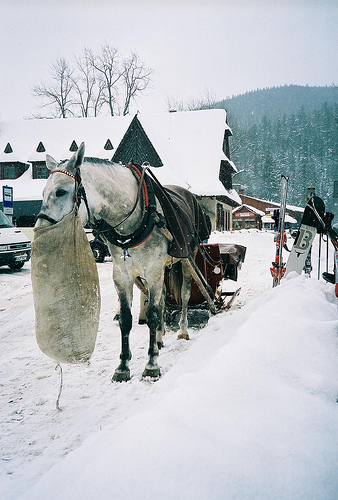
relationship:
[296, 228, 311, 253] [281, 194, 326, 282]
letter on snowboard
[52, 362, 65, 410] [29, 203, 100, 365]
string on feed bag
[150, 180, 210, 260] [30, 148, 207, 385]
blanket over horse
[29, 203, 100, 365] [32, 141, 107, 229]
feed bag on a head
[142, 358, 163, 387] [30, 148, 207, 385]
hoof of horse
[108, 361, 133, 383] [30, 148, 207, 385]
hoof of horse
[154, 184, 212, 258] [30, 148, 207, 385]
blanket over horse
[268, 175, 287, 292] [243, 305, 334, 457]
skis planted in ground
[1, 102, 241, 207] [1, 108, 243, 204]
snow on roof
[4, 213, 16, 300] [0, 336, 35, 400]
van parked nearby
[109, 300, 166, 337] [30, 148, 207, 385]
knees on horse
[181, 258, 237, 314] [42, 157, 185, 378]
sleigh behind horse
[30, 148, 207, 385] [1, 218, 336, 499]
horse on street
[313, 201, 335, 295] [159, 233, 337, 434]
skis standing in snow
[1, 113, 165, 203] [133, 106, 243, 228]
roof on building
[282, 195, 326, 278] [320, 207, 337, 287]
skis on rack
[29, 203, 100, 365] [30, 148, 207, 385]
feed bag on horse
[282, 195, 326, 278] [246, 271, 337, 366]
skis in snow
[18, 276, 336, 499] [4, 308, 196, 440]
snow on street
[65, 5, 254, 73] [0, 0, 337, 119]
sky has clouds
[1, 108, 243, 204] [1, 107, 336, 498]
roof has snow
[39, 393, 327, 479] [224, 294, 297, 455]
ground has snow